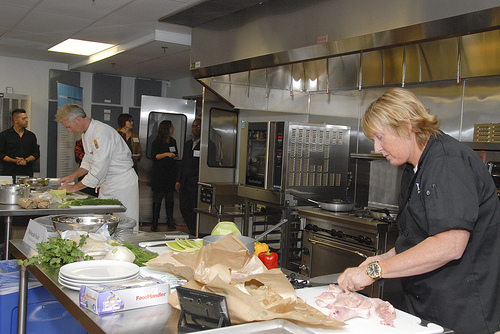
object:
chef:
[58, 104, 140, 234]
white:
[79, 118, 140, 231]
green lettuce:
[17, 232, 95, 271]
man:
[0, 109, 40, 186]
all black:
[0, 125, 40, 179]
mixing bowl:
[202, 235, 256, 257]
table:
[7, 230, 454, 334]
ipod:
[176, 286, 231, 334]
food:
[17, 177, 50, 190]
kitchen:
[0, 0, 499, 333]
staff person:
[175, 118, 201, 236]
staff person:
[151, 120, 180, 232]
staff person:
[116, 113, 142, 175]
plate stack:
[58, 259, 141, 291]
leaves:
[15, 238, 81, 268]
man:
[337, 87, 500, 334]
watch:
[366, 261, 385, 286]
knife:
[309, 273, 345, 284]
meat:
[312, 283, 396, 330]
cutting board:
[286, 283, 454, 334]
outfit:
[80, 118, 140, 231]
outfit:
[394, 128, 500, 318]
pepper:
[258, 249, 278, 270]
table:
[0, 177, 128, 261]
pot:
[0, 184, 31, 205]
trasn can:
[11, 299, 87, 333]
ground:
[0, 264, 20, 327]